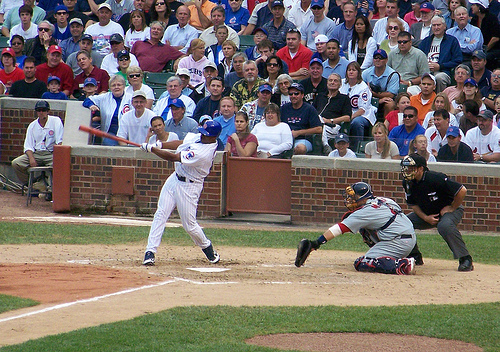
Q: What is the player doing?
A: Swinging a bat.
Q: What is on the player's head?
A: A blue helmet.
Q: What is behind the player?
A: A brick wall.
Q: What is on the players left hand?
A: Catchers mitt.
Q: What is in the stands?
A: Fans watching a game.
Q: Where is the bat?
A: In the batter's hands.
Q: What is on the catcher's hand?
A: A glove.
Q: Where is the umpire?
A: Behind the catcher.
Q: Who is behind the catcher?
A: The umpire.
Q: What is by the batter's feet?
A: Home plate.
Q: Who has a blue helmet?
A: The batter.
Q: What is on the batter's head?
A: A blue helmet.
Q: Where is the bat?
A: In the batter's hands.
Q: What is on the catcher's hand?
A: A glove.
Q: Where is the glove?
A: On the catcher's hand.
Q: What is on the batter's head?
A: A helmet.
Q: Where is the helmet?
A: On the batter's head.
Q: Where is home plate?
A: By the batter's feet.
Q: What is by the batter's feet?
A: Home plate.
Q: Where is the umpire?
A: Behind the catcher.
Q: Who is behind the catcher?
A: The umpire.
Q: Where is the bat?
A: In the batter's hands.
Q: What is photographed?
A: A baseball game.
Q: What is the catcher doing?
A: Grabbing the ball.